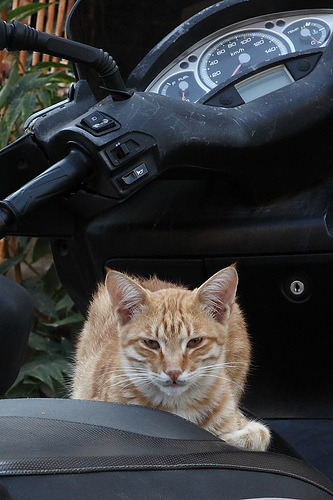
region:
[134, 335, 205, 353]
eyes of a cat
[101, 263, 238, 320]
ears of a cat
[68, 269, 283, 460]
old orange cat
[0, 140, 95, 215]
black handle bar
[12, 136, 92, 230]
handlebar of a motorcycle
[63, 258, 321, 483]
cat sitting on motorcycle seat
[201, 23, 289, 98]
speedometer on a motorcycle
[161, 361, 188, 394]
nose of a cat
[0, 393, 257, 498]
black seat of a motorcycle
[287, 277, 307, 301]
silver key hole on a motorcycle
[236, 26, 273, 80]
part of a mirror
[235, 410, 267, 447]
part fo a paw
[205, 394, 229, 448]
par of a leg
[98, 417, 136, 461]
part of a seat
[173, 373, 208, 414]
part of a mouth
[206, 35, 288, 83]
speedometer of the bike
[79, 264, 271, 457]
a cat sitting in the bike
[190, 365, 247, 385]
mutache of the cat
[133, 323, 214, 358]
eyes looking to the camera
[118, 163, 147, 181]
horn button in the motorcycle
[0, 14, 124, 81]
side mirror handle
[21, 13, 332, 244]
handle bar of the motor cycle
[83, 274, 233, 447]
white and brown color cat sitting in the motorcycle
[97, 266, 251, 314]
ears of the cat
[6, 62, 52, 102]
leaves and plants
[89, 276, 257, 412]
a cat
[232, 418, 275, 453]
the cats paw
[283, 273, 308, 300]
ignition to the car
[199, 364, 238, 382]
the whiskers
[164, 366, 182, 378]
cats nose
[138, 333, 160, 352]
right eye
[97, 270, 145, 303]
the cats ear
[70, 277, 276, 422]
the cat is orange and white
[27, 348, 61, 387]
leaves are green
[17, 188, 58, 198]
a handlebar on the bike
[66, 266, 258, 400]
this is a cat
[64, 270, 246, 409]
the cat is brown in color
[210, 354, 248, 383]
these are the whiskers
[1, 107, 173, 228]
this is the steering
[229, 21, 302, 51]
this is the speedometer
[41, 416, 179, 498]
this is a seat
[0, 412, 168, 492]
the seat is black in color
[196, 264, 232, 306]
this is the ear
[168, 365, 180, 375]
this is the nose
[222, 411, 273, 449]
this is the leg